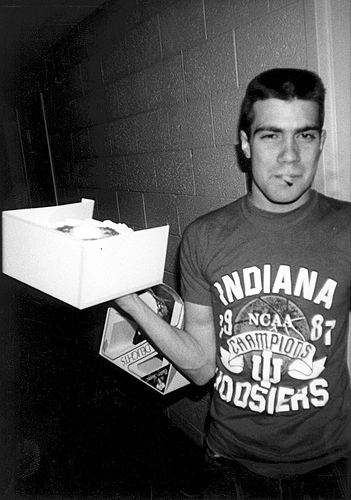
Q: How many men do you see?
A: One.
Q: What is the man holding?
A: A box.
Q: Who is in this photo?
A: A man.